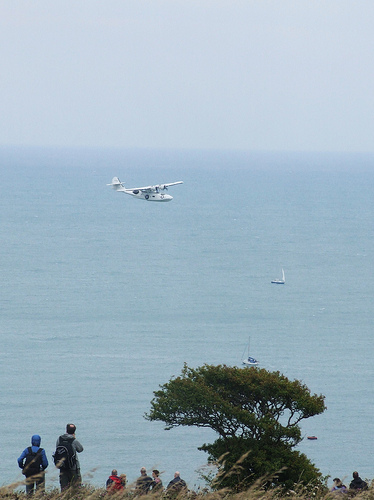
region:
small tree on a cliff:
[140, 350, 336, 484]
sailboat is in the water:
[262, 263, 295, 297]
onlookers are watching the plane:
[29, 427, 192, 493]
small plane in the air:
[99, 157, 205, 208]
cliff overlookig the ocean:
[11, 142, 368, 459]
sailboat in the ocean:
[239, 333, 278, 388]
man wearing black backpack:
[48, 434, 79, 474]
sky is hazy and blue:
[12, 113, 369, 165]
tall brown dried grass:
[15, 468, 359, 498]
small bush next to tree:
[208, 435, 334, 492]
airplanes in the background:
[72, 130, 330, 369]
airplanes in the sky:
[84, 130, 268, 328]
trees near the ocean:
[101, 337, 343, 495]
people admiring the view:
[16, 394, 239, 472]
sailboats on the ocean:
[236, 238, 357, 398]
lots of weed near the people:
[8, 328, 336, 496]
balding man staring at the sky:
[0, 399, 216, 479]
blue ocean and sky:
[26, 167, 331, 445]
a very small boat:
[286, 413, 352, 471]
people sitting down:
[100, 441, 223, 492]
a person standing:
[17, 434, 47, 490]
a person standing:
[50, 416, 85, 494]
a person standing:
[105, 468, 121, 493]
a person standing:
[118, 470, 128, 489]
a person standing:
[137, 463, 154, 498]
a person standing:
[147, 465, 164, 497]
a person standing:
[165, 467, 191, 497]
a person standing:
[324, 472, 347, 495]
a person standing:
[347, 468, 367, 489]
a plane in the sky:
[106, 166, 189, 216]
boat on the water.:
[274, 261, 317, 313]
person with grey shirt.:
[58, 424, 80, 484]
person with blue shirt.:
[20, 429, 44, 488]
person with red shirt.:
[105, 467, 117, 490]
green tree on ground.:
[133, 363, 328, 489]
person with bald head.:
[170, 468, 181, 478]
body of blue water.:
[38, 256, 172, 405]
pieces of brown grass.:
[199, 468, 295, 496]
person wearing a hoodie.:
[19, 420, 55, 495]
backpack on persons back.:
[53, 431, 82, 479]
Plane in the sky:
[92, 151, 189, 226]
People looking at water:
[15, 425, 95, 490]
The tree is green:
[142, 368, 316, 495]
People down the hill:
[100, 464, 190, 498]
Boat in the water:
[246, 266, 299, 306]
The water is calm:
[150, 324, 309, 419]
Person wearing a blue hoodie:
[14, 432, 58, 477]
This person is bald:
[57, 413, 88, 469]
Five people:
[107, 449, 195, 498]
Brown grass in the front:
[121, 471, 240, 499]